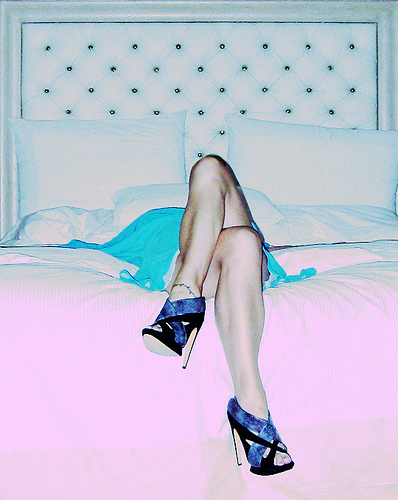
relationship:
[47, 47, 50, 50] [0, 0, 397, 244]
nail in headboard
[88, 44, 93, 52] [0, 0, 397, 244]
nail in headboard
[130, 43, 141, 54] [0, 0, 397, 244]
nail in headboard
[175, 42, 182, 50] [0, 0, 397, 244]
nail in headboard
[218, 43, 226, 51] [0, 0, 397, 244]
nail in headboard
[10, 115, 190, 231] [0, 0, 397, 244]
pillow by headboard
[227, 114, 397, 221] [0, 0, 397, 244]
pillow by headboard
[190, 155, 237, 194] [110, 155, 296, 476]
knee of woman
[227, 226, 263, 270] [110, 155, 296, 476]
knee of woman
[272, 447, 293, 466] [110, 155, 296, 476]
toes of woman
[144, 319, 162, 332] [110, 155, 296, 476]
toes of woman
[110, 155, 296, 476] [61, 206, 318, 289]
woman wearing dress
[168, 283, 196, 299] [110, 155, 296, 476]
tattoo on woman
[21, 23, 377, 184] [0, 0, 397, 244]
lines on headboard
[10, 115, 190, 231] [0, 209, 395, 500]
pillow on cover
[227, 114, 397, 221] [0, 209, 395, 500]
pillow on cover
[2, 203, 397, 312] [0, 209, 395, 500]
lines in cover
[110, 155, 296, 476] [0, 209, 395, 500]
woman on cover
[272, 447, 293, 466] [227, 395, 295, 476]
toes in shoe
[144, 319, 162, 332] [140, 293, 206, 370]
toes in shoe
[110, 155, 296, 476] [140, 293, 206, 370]
woman wearing shoe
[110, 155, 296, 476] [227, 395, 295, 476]
woman wearing shoe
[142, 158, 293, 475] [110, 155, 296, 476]
legs of woman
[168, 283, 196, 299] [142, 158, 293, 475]
tattoo on legs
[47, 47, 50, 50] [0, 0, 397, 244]
nail on headboard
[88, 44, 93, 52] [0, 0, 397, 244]
nail on headboard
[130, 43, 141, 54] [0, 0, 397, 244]
nail on headboard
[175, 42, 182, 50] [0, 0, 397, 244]
nail on headboard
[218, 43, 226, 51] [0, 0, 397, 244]
nail on headboard